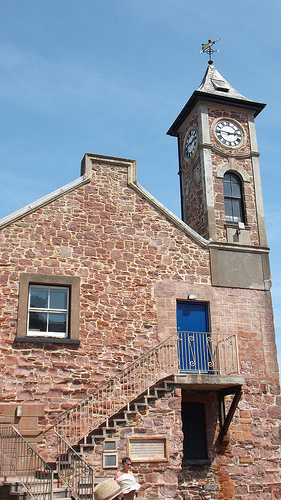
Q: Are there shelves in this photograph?
A: No, there are no shelves.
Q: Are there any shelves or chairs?
A: No, there are no shelves or chairs.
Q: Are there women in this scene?
A: Yes, there is a woman.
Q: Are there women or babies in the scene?
A: Yes, there is a woman.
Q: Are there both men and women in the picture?
A: No, there is a woman but no men.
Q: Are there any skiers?
A: No, there are no skiers.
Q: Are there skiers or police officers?
A: No, there are no skiers or police officers.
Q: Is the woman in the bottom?
A: Yes, the woman is in the bottom of the image.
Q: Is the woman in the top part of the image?
A: No, the woman is in the bottom of the image.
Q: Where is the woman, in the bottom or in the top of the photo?
A: The woman is in the bottom of the image.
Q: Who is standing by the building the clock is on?
A: The woman is standing by the building.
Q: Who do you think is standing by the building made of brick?
A: The woman is standing by the building.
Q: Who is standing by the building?
A: The woman is standing by the building.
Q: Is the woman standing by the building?
A: Yes, the woman is standing by the building.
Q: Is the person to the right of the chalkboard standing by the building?
A: Yes, the woman is standing by the building.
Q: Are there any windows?
A: Yes, there is a window.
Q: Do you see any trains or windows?
A: Yes, there is a window.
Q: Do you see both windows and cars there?
A: No, there is a window but no cars.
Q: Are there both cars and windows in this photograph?
A: No, there is a window but no cars.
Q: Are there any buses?
A: No, there are no buses.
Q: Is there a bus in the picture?
A: No, there are no buses.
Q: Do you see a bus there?
A: No, there are no buses.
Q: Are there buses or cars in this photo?
A: No, there are no buses or cars.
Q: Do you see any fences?
A: No, there are no fences.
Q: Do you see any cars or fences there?
A: No, there are no fences or cars.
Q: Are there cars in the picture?
A: No, there are no cars.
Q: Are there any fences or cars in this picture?
A: No, there are no cars or fences.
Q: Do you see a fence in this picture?
A: No, there are no fences.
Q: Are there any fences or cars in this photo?
A: No, there are no fences or cars.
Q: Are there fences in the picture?
A: No, there are no fences.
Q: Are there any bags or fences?
A: No, there are no fences or bags.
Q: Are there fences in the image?
A: No, there are no fences.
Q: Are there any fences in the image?
A: No, there are no fences.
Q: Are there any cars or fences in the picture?
A: No, there are no fences or cars.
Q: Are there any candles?
A: No, there are no candles.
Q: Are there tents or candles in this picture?
A: No, there are no candles or tents.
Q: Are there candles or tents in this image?
A: No, there are no candles or tents.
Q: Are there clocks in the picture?
A: Yes, there is a clock.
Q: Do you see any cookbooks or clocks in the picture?
A: Yes, there is a clock.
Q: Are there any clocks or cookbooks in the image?
A: Yes, there is a clock.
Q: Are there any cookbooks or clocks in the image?
A: Yes, there is a clock.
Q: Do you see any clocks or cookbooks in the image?
A: Yes, there is a clock.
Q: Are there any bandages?
A: No, there are no bandages.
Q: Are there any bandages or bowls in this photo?
A: No, there are no bandages or bowls.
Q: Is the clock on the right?
A: Yes, the clock is on the right of the image.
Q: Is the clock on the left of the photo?
A: No, the clock is on the right of the image.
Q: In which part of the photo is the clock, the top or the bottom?
A: The clock is in the top of the image.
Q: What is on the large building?
A: The clock is on the building.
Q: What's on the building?
A: The clock is on the building.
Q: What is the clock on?
A: The clock is on the building.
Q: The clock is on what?
A: The clock is on the building.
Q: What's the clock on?
A: The clock is on the building.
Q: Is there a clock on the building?
A: Yes, there is a clock on the building.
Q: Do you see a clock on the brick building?
A: Yes, there is a clock on the building.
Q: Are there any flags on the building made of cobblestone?
A: No, there is a clock on the building.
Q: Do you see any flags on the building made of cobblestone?
A: No, there is a clock on the building.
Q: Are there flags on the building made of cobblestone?
A: No, there is a clock on the building.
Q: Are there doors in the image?
A: Yes, there is a door.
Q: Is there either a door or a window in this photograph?
A: Yes, there is a door.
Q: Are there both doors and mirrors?
A: No, there is a door but no mirrors.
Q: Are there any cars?
A: No, there are no cars.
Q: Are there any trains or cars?
A: No, there are no cars or trains.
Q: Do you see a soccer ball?
A: No, there are no soccer balls.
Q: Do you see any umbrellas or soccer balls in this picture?
A: No, there are no soccer balls or umbrellas.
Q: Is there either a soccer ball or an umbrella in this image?
A: No, there are no soccer balls or umbrellas.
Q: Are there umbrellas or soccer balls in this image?
A: No, there are no soccer balls or umbrellas.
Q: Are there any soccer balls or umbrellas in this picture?
A: No, there are no soccer balls or umbrellas.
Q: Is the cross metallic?
A: Yes, the cross is metallic.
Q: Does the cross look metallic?
A: Yes, the cross is metallic.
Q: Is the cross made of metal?
A: Yes, the cross is made of metal.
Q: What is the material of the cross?
A: The cross is made of metal.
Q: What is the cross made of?
A: The cross is made of metal.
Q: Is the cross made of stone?
A: No, the cross is made of metal.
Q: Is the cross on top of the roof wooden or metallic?
A: The cross is metallic.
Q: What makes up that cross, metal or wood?
A: The cross is made of metal.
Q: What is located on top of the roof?
A: The cross is on top of the roof.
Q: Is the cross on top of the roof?
A: Yes, the cross is on top of the roof.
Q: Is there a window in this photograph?
A: Yes, there is a window.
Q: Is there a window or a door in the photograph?
A: Yes, there is a window.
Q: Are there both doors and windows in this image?
A: Yes, there are both a window and a door.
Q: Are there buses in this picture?
A: No, there are no buses.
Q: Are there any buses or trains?
A: No, there are no buses or trains.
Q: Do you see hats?
A: Yes, there is a hat.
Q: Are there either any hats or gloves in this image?
A: Yes, there is a hat.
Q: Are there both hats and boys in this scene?
A: No, there is a hat but no boys.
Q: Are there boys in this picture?
A: No, there are no boys.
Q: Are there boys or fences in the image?
A: No, there are no boys or fences.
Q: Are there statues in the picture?
A: No, there are no statues.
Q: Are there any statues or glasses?
A: No, there are no statues or glasses.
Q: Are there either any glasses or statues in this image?
A: No, there are no statues or glasses.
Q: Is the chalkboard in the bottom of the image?
A: Yes, the chalkboard is in the bottom of the image.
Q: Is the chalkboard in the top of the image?
A: No, the chalkboard is in the bottom of the image.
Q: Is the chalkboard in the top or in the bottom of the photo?
A: The chalkboard is in the bottom of the image.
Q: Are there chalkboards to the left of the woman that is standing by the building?
A: Yes, there is a chalkboard to the left of the woman.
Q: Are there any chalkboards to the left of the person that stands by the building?
A: Yes, there is a chalkboard to the left of the woman.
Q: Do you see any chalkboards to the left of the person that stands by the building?
A: Yes, there is a chalkboard to the left of the woman.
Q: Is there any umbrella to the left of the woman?
A: No, there is a chalkboard to the left of the woman.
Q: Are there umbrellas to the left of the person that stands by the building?
A: No, there is a chalkboard to the left of the woman.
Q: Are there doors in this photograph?
A: Yes, there is a door.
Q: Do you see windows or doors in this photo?
A: Yes, there is a door.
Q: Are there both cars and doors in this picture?
A: No, there is a door but no cars.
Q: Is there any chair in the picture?
A: No, there are no chairs.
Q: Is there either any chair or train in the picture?
A: No, there are no chairs or trains.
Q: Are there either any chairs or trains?
A: No, there are no chairs or trains.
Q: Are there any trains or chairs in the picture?
A: No, there are no chairs or trains.